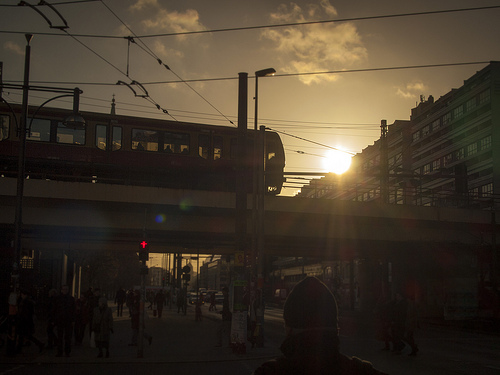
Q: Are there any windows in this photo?
A: Yes, there are windows.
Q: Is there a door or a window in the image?
A: Yes, there are windows.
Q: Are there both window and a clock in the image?
A: No, there are windows but no clocks.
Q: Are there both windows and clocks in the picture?
A: No, there are windows but no clocks.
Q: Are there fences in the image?
A: No, there are no fences.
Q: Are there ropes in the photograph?
A: No, there are no ropes.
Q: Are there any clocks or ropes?
A: No, there are no ropes or clocks.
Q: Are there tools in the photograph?
A: No, there are no tools.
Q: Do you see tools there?
A: No, there are no tools.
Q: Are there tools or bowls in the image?
A: No, there are no tools or bowls.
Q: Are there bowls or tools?
A: No, there are no tools or bowls.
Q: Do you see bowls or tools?
A: No, there are no tools or bowls.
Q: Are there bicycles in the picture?
A: No, there are no bicycles.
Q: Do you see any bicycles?
A: No, there are no bicycles.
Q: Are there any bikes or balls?
A: No, there are no bikes or balls.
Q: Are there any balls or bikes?
A: No, there are no bikes or balls.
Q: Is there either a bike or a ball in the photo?
A: No, there are no bikes or balls.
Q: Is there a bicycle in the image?
A: No, there are no bicycles.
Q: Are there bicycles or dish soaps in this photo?
A: No, there are no bicycles or dish soaps.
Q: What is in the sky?
A: The clouds are in the sky.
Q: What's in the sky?
A: The clouds are in the sky.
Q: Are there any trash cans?
A: No, there are no trash cans.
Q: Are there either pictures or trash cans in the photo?
A: No, there are no trash cans or pictures.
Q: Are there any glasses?
A: No, there are no glasses.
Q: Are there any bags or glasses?
A: No, there are no glasses or bags.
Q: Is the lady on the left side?
A: Yes, the lady is on the left of the image.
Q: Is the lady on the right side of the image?
A: No, the lady is on the left of the image.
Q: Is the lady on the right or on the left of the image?
A: The lady is on the left of the image.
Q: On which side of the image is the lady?
A: The lady is on the left of the image.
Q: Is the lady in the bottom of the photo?
A: Yes, the lady is in the bottom of the image.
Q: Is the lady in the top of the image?
A: No, the lady is in the bottom of the image.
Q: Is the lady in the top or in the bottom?
A: The lady is in the bottom of the image.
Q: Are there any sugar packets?
A: No, there are no sugar packets.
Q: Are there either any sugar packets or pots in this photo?
A: No, there are no sugar packets or pots.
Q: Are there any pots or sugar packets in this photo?
A: No, there are no sugar packets or pots.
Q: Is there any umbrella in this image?
A: No, there are no umbrellas.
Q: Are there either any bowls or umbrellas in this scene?
A: No, there are no umbrellas or bowls.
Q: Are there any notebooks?
A: No, there are no notebooks.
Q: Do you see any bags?
A: No, there are no bags.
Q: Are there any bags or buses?
A: No, there are no bags or buses.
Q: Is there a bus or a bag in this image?
A: No, there are no bags or buses.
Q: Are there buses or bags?
A: No, there are no bags or buses.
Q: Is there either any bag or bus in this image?
A: No, there are no bags or buses.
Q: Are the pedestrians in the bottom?
A: Yes, the pedestrians are in the bottom of the image.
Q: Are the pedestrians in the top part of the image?
A: No, the pedestrians are in the bottom of the image.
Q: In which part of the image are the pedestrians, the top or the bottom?
A: The pedestrians are in the bottom of the image.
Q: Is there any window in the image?
A: Yes, there is a window.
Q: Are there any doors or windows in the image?
A: Yes, there is a window.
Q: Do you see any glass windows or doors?
A: Yes, there is a glass window.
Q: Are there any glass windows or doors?
A: Yes, there is a glass window.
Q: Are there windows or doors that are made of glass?
A: Yes, the window is made of glass.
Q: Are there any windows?
A: Yes, there is a window.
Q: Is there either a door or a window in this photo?
A: Yes, there is a window.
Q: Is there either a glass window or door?
A: Yes, there is a glass window.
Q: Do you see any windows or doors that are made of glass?
A: Yes, the window is made of glass.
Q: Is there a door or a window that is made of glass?
A: Yes, the window is made of glass.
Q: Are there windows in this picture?
A: Yes, there is a window.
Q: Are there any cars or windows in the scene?
A: Yes, there is a window.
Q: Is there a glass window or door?
A: Yes, there is a glass window.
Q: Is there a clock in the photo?
A: No, there are no clocks.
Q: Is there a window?
A: Yes, there is a window.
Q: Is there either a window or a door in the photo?
A: Yes, there is a window.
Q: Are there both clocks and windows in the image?
A: No, there is a window but no clocks.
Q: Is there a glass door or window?
A: Yes, there is a glass window.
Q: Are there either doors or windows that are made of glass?
A: Yes, the window is made of glass.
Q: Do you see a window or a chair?
A: Yes, there is a window.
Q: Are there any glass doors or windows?
A: Yes, there is a glass window.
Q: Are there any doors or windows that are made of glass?
A: Yes, the window is made of glass.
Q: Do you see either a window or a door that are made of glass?
A: Yes, the window is made of glass.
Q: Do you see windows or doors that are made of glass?
A: Yes, the window is made of glass.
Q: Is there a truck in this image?
A: No, there are no trucks.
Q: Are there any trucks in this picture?
A: No, there are no trucks.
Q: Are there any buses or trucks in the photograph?
A: No, there are no trucks or buses.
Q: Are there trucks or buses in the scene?
A: No, there are no trucks or buses.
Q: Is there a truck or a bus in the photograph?
A: No, there are no trucks or buses.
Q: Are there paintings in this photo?
A: No, there are no paintings.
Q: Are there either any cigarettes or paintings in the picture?
A: No, there are no paintings or cigarettes.